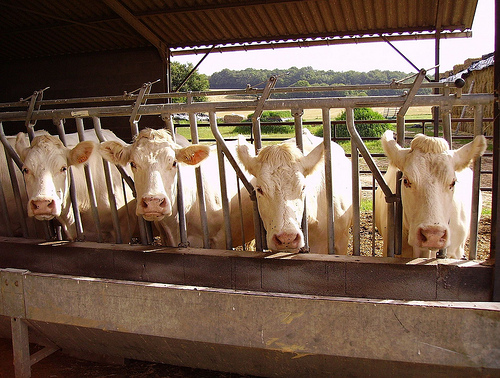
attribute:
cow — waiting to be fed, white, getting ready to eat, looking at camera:
[112, 120, 261, 238]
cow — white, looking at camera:
[29, 125, 130, 236]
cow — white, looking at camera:
[235, 134, 367, 261]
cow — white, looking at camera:
[368, 122, 480, 275]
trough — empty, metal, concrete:
[2, 213, 492, 374]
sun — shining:
[475, 5, 494, 23]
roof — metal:
[3, 1, 477, 59]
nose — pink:
[135, 192, 172, 213]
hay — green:
[317, 105, 395, 142]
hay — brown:
[443, 65, 494, 136]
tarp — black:
[429, 41, 499, 84]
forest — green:
[197, 66, 418, 94]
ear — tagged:
[94, 140, 138, 168]